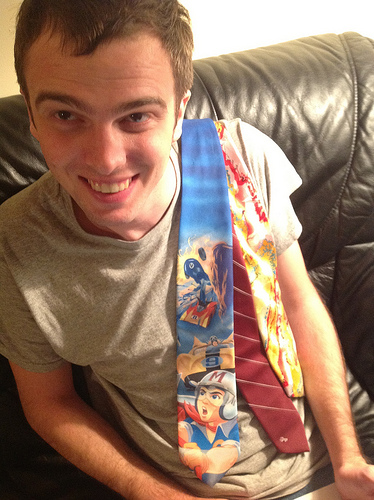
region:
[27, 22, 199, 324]
face of the person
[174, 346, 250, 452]
a man wearing tie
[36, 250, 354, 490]
a man wearing shirt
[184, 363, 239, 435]
a design on tie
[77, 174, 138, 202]
smile exposing very white teeth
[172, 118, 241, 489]
necktie picturing a car racing accident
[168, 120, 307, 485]
3 very different neckties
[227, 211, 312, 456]
dark red necktie with horizontal stripes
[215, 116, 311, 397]
yellow and red printed necktie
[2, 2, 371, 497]
smiling young man wearing a gray t-shirt and showing off 3 neckties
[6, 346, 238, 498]
young man's arm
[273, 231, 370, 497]
young man's left arm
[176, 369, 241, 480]
cartoon race car driver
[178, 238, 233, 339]
cartoon racing car accident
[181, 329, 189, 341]
blue on mans tie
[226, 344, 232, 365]
orange on mans tie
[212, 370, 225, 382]
letter m on helmet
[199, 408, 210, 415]
mans mouth is open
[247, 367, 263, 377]
burgandy color on tie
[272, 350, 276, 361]
yellow color on tie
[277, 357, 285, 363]
red color on tie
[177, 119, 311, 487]
3 neck ties draped over shoulder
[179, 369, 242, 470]
Speed Racer with open mouth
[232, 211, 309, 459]
Red neck tie with white stripes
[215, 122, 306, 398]
Yellow, red, and white print tie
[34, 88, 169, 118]
Eye brows extending over nose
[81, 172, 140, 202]
Smiling mouth showing teeth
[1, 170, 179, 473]
Gray cotton tee shirt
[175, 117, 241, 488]
Tie with Speed Racer characters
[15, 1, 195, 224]
Young man's head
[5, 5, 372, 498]
man sitting on leather couch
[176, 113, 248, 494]
blue tie with animation design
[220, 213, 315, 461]
maroon tie with gold stripes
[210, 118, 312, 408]
yellow,white and gold design on man's shoulder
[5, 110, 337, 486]
grey short sleeve t-shirt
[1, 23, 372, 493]
black leather seating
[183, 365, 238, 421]
helmet on anmated character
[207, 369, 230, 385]
red letter "M" on helmet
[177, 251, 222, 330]
blue bird in race car on tie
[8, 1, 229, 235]
man smiling with two ties over his shoulder